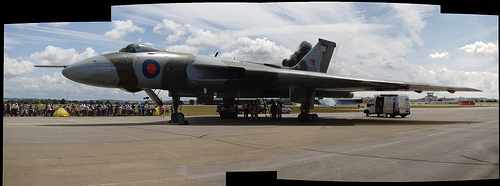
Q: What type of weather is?
A: It is cloudy.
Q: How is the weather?
A: It is cloudy.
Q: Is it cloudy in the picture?
A: Yes, it is cloudy.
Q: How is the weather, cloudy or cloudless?
A: It is cloudy.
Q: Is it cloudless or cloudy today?
A: It is cloudy.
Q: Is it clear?
A: No, it is cloudy.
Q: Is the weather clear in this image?
A: No, it is cloudy.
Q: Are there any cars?
A: No, there are no cars.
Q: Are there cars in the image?
A: No, there are no cars.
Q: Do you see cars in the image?
A: No, there are no cars.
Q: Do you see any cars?
A: No, there are no cars.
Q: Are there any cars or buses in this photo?
A: No, there are no cars or buses.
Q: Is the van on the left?
A: No, the van is on the right of the image.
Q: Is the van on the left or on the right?
A: The van is on the right of the image.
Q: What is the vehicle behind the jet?
A: The vehicle is a van.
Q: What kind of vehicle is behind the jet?
A: The vehicle is a van.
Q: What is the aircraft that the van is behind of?
A: The aircraft is a jet.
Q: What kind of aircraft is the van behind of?
A: The van is behind the jet.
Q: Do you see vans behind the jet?
A: Yes, there is a van behind the jet.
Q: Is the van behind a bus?
A: No, the van is behind the jet.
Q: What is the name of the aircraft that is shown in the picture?
A: The aircraft is a jet.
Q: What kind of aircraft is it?
A: The aircraft is a jet.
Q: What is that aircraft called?
A: This is a jet.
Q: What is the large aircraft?
A: The aircraft is a jet.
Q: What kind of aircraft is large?
A: The aircraft is a jet.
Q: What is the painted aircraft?
A: The aircraft is a jet.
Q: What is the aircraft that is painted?
A: The aircraft is a jet.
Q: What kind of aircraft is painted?
A: The aircraft is a jet.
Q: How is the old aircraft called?
A: The aircraft is a jet.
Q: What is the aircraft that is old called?
A: The aircraft is a jet.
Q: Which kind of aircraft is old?
A: The aircraft is a jet.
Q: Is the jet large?
A: Yes, the jet is large.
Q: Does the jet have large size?
A: Yes, the jet is large.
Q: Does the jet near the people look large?
A: Yes, the jet is large.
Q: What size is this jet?
A: The jet is large.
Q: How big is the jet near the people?
A: The jet is large.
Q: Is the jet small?
A: No, the jet is large.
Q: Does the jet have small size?
A: No, the jet is large.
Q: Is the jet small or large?
A: The jet is large.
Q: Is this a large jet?
A: Yes, this is a large jet.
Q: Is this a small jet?
A: No, this is a large jet.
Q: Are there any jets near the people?
A: Yes, there is a jet near the people.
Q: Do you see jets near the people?
A: Yes, there is a jet near the people.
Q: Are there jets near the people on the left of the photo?
A: Yes, there is a jet near the people.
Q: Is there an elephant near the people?
A: No, there is a jet near the people.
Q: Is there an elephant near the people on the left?
A: No, there is a jet near the people.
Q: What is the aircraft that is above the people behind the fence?
A: The aircraft is a jet.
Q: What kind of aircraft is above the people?
A: The aircraft is a jet.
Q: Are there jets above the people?
A: Yes, there is a jet above the people.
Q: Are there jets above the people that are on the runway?
A: Yes, there is a jet above the people.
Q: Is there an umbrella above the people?
A: No, there is a jet above the people.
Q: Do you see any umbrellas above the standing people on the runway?
A: No, there is a jet above the people.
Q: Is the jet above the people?
A: Yes, the jet is above the people.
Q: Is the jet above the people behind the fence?
A: Yes, the jet is above the people.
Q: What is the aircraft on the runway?
A: The aircraft is a jet.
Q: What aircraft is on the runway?
A: The aircraft is a jet.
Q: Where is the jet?
A: The jet is on the runway.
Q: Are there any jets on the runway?
A: Yes, there is a jet on the runway.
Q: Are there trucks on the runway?
A: No, there is a jet on the runway.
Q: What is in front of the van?
A: The jet is in front of the van.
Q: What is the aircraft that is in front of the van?
A: The aircraft is a jet.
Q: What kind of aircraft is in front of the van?
A: The aircraft is a jet.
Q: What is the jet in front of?
A: The jet is in front of the van.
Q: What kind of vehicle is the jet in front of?
A: The jet is in front of the van.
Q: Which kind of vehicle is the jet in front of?
A: The jet is in front of the van.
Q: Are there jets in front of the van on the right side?
A: Yes, there is a jet in front of the van.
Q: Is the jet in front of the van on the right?
A: Yes, the jet is in front of the van.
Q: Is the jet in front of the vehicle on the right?
A: Yes, the jet is in front of the van.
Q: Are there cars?
A: No, there are no cars.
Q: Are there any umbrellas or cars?
A: No, there are no cars or umbrellas.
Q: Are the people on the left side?
A: Yes, the people are on the left of the image.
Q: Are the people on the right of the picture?
A: No, the people are on the left of the image.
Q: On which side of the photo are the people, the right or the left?
A: The people are on the left of the image.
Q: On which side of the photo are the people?
A: The people are on the left of the image.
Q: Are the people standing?
A: Yes, the people are standing.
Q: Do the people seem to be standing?
A: Yes, the people are standing.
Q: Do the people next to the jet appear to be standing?
A: Yes, the people are standing.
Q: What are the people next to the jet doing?
A: The people are standing.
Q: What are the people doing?
A: The people are standing.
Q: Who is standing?
A: The people are standing.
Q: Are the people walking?
A: No, the people are standing.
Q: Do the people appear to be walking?
A: No, the people are standing.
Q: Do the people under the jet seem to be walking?
A: No, the people are standing.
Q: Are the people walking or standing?
A: The people are standing.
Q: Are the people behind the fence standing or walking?
A: The people are standing.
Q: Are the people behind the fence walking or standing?
A: The people are standing.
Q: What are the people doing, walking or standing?
A: The people are standing.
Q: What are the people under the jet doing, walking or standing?
A: The people are standing.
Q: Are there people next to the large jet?
A: Yes, there are people next to the jet.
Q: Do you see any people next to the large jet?
A: Yes, there are people next to the jet.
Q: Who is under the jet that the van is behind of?
A: The people are under the jet.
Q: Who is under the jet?
A: The people are under the jet.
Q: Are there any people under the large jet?
A: Yes, there are people under the jet.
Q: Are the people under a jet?
A: Yes, the people are under a jet.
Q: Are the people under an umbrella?
A: No, the people are under a jet.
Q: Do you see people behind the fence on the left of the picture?
A: Yes, there are people behind the fence.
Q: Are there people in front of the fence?
A: No, the people are behind the fence.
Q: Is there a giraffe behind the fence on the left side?
A: No, there are people behind the fence.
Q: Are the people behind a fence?
A: Yes, the people are behind a fence.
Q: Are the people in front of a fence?
A: No, the people are behind a fence.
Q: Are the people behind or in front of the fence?
A: The people are behind the fence.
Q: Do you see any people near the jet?
A: Yes, there are people near the jet.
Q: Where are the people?
A: The people are on the runway.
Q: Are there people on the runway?
A: Yes, there are people on the runway.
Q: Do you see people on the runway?
A: Yes, there are people on the runway.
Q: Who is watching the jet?
A: The people are watching the jet.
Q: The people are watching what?
A: The people are watching the jet.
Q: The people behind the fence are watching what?
A: The people are watching the jet.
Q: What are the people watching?
A: The people are watching the jet.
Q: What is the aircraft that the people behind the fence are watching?
A: The aircraft is a jet.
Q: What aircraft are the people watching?
A: The people are watching the jet.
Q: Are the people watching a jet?
A: Yes, the people are watching a jet.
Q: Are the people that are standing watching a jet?
A: Yes, the people are watching a jet.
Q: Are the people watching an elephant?
A: No, the people are watching a jet.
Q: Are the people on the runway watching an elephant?
A: No, the people are watching a jet.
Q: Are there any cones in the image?
A: No, there are no cones.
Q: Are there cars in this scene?
A: No, there are no cars.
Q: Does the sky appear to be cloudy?
A: Yes, the sky is cloudy.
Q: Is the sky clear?
A: No, the sky is cloudy.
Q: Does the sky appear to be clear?
A: No, the sky is cloudy.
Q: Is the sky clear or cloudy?
A: The sky is cloudy.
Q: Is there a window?
A: Yes, there is a window.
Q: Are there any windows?
A: Yes, there is a window.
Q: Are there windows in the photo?
A: Yes, there is a window.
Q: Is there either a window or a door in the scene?
A: Yes, there is a window.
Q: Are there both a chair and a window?
A: No, there is a window but no chairs.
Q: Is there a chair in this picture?
A: No, there are no chairs.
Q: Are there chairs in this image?
A: No, there are no chairs.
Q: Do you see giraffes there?
A: No, there are no giraffes.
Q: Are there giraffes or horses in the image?
A: No, there are no giraffes or horses.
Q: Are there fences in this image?
A: Yes, there is a fence.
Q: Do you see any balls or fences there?
A: Yes, there is a fence.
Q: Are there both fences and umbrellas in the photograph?
A: No, there is a fence but no umbrellas.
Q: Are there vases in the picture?
A: No, there are no vases.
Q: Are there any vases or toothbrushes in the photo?
A: No, there are no vases or toothbrushes.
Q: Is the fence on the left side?
A: Yes, the fence is on the left of the image.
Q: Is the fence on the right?
A: No, the fence is on the left of the image.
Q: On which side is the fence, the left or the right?
A: The fence is on the left of the image.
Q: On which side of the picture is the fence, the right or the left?
A: The fence is on the left of the image.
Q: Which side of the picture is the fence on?
A: The fence is on the left of the image.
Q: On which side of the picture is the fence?
A: The fence is on the left of the image.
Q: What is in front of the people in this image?
A: The fence is in front of the people.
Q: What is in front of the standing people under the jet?
A: The fence is in front of the people.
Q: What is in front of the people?
A: The fence is in front of the people.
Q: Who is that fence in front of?
A: The fence is in front of the people.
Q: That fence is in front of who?
A: The fence is in front of the people.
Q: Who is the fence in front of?
A: The fence is in front of the people.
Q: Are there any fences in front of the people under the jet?
A: Yes, there is a fence in front of the people.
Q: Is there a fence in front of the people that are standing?
A: Yes, there is a fence in front of the people.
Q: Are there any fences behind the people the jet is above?
A: No, the fence is in front of the people.